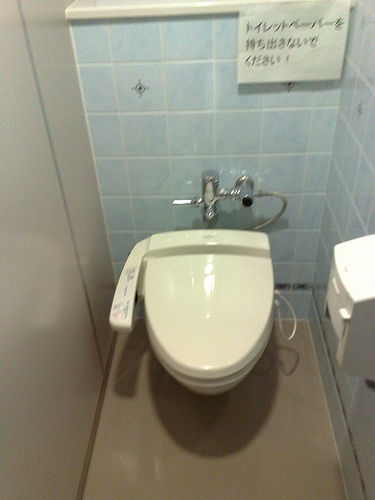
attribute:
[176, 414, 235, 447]
shadow — dark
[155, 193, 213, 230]
handle — toilet handle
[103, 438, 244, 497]
floor — brown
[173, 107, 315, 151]
tile — blue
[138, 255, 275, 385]
seat — down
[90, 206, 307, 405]
toilet — shiny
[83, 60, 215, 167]
tiles — light blue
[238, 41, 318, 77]
writing — in japanese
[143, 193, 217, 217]
handle — silver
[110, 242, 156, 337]
controls — white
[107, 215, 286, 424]
seat — white, lid seat, toilet seat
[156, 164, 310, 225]
silverware — hard metal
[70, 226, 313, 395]
toilet — white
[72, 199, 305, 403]
toilet — white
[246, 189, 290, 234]
toilet hose — grey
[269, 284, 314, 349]
cord — grey, on the right side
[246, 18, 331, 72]
writing — black, chinese writing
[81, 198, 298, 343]
flusher handle — shiny silver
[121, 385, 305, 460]
shadow — of the toilet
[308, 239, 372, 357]
container — toilet paper container 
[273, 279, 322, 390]
tube — on the right side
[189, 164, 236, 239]
pipe — silver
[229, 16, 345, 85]
writing — foreign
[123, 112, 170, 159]
tile — blue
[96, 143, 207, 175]
grout — white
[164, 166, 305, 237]
toilet piping — chrome colored